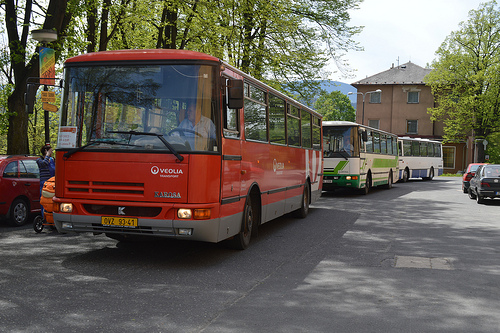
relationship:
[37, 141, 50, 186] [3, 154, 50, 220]
person next to car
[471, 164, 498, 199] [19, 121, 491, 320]
car parked on street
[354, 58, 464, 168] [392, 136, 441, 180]
building behind bus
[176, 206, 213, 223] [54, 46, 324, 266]
lights on bus